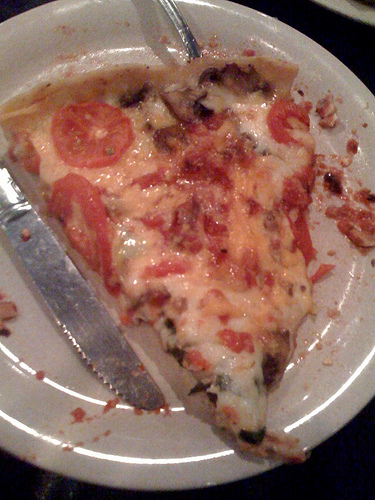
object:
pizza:
[0, 52, 327, 464]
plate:
[0, 0, 374, 490]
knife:
[0, 156, 166, 411]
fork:
[157, 0, 206, 62]